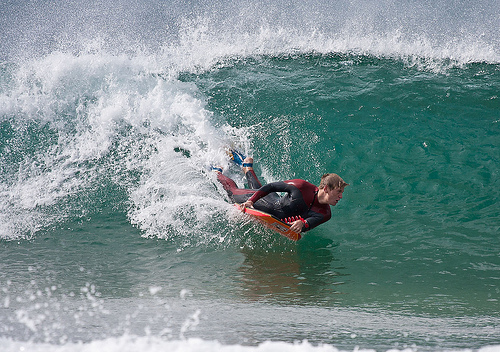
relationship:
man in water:
[214, 158, 345, 231] [358, 112, 498, 243]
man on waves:
[214, 158, 345, 231] [3, 37, 499, 88]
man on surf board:
[214, 158, 345, 231] [237, 208, 300, 243]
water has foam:
[358, 112, 498, 243] [112, 75, 184, 114]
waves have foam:
[3, 37, 499, 88] [112, 75, 184, 114]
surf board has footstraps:
[237, 208, 300, 243] [207, 150, 250, 173]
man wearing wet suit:
[214, 158, 345, 231] [213, 172, 334, 230]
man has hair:
[214, 158, 345, 231] [320, 173, 349, 188]